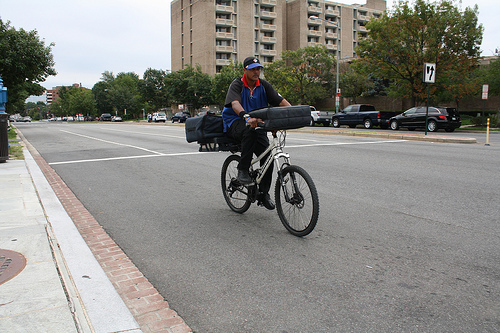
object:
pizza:
[238, 106, 316, 132]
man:
[222, 56, 299, 185]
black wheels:
[221, 154, 320, 238]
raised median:
[351, 123, 470, 157]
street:
[13, 116, 500, 332]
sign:
[425, 62, 437, 82]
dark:
[389, 105, 462, 134]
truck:
[329, 103, 462, 134]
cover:
[0, 249, 28, 285]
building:
[171, 1, 288, 79]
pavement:
[10, 120, 198, 333]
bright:
[483, 112, 492, 149]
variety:
[84, 72, 179, 117]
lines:
[47, 127, 178, 165]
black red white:
[241, 54, 262, 72]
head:
[243, 56, 268, 81]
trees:
[44, 33, 486, 121]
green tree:
[93, 70, 162, 121]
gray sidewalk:
[0, 147, 139, 333]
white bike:
[250, 130, 288, 192]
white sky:
[0, 0, 172, 106]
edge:
[14, 139, 85, 222]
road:
[93, 136, 151, 180]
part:
[215, 154, 242, 217]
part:
[116, 152, 176, 178]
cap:
[243, 56, 270, 73]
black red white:
[219, 73, 282, 118]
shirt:
[224, 79, 307, 130]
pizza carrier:
[239, 94, 316, 135]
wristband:
[236, 110, 249, 119]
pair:
[223, 105, 272, 188]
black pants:
[230, 119, 269, 170]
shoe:
[227, 168, 255, 186]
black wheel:
[274, 165, 320, 237]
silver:
[224, 150, 293, 188]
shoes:
[237, 169, 276, 211]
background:
[138, 72, 330, 115]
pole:
[481, 126, 484, 153]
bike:
[220, 123, 320, 236]